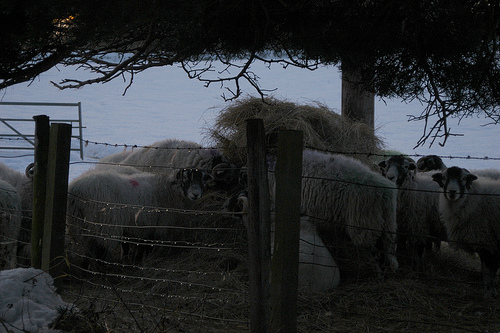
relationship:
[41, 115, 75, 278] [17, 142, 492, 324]
post on fence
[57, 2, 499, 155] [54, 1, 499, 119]
tree has leaves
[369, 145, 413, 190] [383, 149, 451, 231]
head of sheep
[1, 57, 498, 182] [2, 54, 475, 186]
snow on ground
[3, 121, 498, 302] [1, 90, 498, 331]
sheep herd in pen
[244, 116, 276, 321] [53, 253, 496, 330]
post on ground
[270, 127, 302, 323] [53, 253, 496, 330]
post on ground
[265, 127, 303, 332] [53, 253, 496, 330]
post on ground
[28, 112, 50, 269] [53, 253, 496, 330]
post on ground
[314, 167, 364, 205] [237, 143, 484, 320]
hair on body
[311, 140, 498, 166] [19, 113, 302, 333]
wire of fence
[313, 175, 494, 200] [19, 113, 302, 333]
wire of fence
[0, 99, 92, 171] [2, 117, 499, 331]
gate of fence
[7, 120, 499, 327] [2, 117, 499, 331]
sheep on other side of fence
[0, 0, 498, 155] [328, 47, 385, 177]
tree has post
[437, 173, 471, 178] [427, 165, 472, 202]
ears on sides of head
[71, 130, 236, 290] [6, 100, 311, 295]
wires running between posts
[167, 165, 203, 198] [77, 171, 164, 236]
black head on white body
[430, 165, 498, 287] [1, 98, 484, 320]
sheep inside of pen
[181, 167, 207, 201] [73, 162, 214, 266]
face of sheep